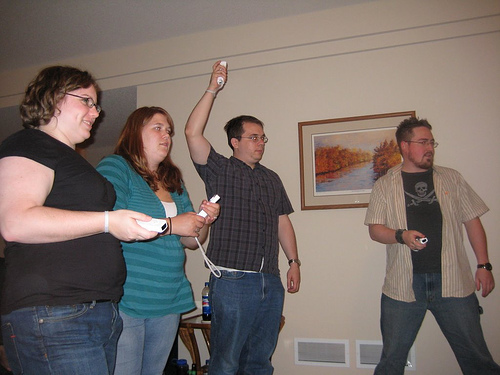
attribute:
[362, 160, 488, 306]
shirt — black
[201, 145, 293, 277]
shirt — black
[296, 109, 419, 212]
picture frame — brown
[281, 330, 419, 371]
vents — white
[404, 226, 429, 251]
controller — white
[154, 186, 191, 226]
shirt — white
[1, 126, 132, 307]
shirt — black 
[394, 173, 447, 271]
shirt — white, black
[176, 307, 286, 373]
table — small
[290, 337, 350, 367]
vent — white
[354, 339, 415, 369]
vent — white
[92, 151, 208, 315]
shirt — striped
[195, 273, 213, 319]
bottle — blue